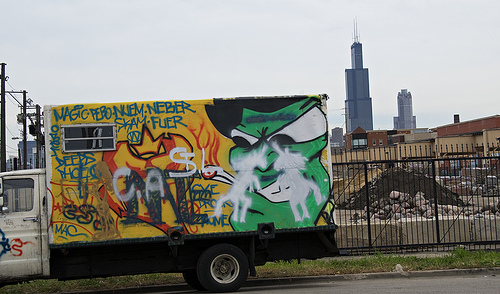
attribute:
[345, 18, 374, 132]
skyscraper — tall, building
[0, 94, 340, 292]
truck — parked, painted, box, white, on a downhill grade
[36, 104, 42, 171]
pole — brown, telephones, utility, tall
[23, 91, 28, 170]
pole — brown, telephones, utility, tall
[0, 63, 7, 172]
pole — brown, telephones, utility, tall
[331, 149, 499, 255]
fence — black, metal, iron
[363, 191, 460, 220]
pile — debris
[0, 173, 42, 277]
door — white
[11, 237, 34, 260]
graffiti — red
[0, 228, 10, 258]
graffiti — blue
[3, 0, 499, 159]
sky — light blue, overcast, white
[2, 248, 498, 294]
grass — small, green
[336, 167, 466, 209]
pile — dirt, large, brown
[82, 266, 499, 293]
road — grey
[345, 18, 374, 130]
building — tall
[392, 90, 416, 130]
building — tall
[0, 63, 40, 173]
poles — telephones, in a row, brown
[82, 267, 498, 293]
curb — concrete, broken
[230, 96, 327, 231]
face — green, large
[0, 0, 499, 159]
skies — gloomy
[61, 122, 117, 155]
window — rectangle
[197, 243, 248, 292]
tire — back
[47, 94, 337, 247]
decoration — colorful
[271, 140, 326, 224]
unicorn — dancing together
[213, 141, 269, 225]
unicorn — dancing together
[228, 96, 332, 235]
caricature — green, a face, a creature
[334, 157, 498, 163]
rail — black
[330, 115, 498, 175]
building — brown